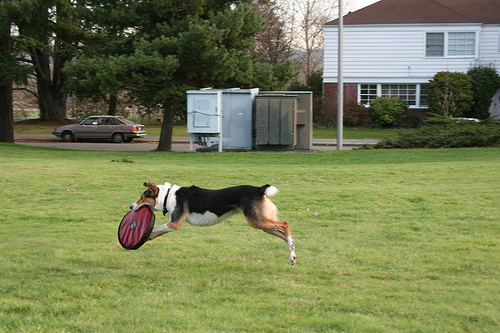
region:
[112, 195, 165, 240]
Red cloth frisbee in dog's mouth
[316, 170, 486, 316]
green freshly cut grass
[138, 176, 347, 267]
Dog in mid air holding frisbee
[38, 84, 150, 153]
Old car across the street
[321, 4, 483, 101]
Red and white brick and wood building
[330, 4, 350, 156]
concrete telephone pole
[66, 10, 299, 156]
Trees located on roadside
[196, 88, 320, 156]
grey and brown electrical stations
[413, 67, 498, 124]
Bushes along side house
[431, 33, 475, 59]
Windows on house with glass panes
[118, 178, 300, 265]
Dog with frisbee in his mouth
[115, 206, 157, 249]
Red and black frisbee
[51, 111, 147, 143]
Light brown car parked on street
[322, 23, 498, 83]
White part of house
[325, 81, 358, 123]
Brick part of house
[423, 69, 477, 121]
Big bush on side of house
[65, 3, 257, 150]
Tall tree on side of road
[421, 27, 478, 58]
Windows on upper floor of white house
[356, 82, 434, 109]
Windows on lst floor on house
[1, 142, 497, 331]
Grass dog is playing on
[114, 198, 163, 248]
Cloth Frisby for dogs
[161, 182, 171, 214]
Collar on a dog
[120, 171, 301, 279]
Dog playing frisbee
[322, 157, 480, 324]
Large grassy field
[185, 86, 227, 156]
Utility box on support posts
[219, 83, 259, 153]
Trash dumpster next to utility box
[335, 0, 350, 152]
Utility pole anchored in ground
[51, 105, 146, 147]
Car parked on the street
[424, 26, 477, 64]
Upstairs window on apartment building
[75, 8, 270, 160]
Large evergreen tree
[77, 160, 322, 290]
a dog jumping high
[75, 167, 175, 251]
dog with frisbee in the mouth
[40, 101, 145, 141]
a gold parked car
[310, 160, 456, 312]
a field of green healthy grass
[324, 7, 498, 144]
a house in the background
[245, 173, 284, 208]
the dog`s fluffy white tail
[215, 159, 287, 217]
the dog`s tail is short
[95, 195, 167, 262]
the frisbee is in a case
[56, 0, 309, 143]
tall bushy green tree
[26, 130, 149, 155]
the street is grey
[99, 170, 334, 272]
The dog is running.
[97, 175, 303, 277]
The dog is carrying a frisbee.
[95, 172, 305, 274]
The dog has a short tail.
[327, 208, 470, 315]
The ground is covered in grass.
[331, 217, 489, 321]
The grass is green.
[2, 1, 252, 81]
The trees are green.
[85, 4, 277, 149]
Trees are in the background.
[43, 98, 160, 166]
Cars are in the background.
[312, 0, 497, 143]
Buildings are in the background.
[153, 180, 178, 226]
The dog is wearing a collar.